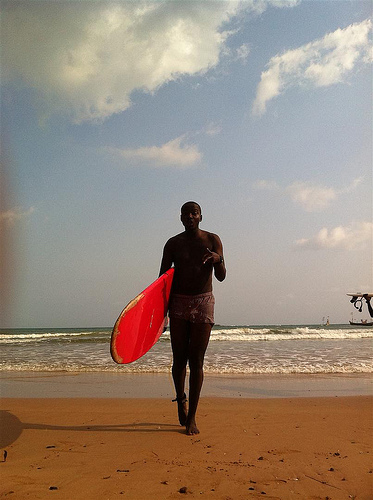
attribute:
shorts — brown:
[134, 279, 237, 341]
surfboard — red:
[105, 243, 175, 367]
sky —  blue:
[195, 49, 319, 175]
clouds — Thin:
[101, 135, 209, 185]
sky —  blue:
[138, 90, 226, 136]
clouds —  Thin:
[245, 8, 370, 120]